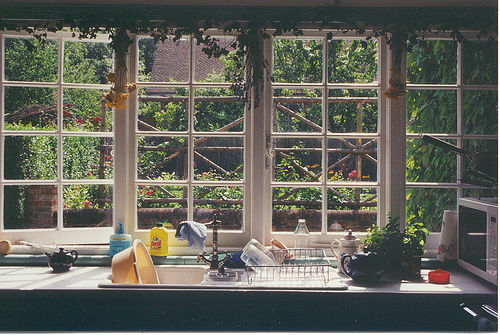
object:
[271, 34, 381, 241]
white window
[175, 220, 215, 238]
faucet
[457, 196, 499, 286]
microoven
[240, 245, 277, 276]
bottles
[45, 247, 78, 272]
tea pot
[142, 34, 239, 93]
house roof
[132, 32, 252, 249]
window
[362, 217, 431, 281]
houseplant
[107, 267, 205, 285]
sink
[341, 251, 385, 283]
tea pot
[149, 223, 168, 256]
bottle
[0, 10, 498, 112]
plants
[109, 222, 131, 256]
bottle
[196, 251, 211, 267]
handle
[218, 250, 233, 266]
handle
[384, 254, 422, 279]
pot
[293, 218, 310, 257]
bottle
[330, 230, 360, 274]
jar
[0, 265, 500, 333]
counter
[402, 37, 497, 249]
window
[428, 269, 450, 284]
tin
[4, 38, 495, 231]
plants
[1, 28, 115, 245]
window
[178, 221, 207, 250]
dish cloth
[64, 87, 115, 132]
window pane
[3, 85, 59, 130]
window pane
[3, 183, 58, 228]
window pane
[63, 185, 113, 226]
window pane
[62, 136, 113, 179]
window pane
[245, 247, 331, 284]
dish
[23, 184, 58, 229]
pillar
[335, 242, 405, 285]
sitting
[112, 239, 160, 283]
bain